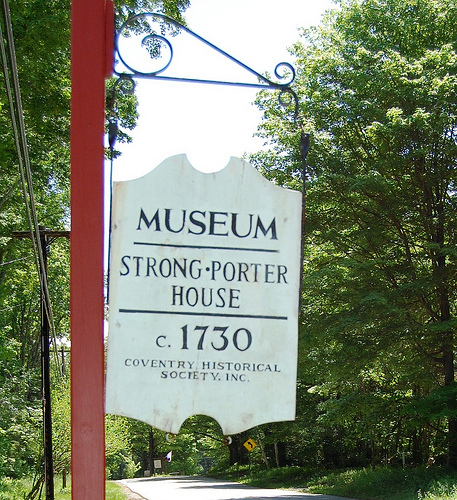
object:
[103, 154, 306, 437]
sign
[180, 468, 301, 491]
shadow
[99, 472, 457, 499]
ground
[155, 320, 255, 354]
year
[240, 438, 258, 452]
sign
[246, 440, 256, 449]
area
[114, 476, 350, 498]
road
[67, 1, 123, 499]
red metal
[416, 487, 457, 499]
grass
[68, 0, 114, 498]
post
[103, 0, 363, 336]
sky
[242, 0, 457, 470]
clump trees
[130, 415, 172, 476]
tree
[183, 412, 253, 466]
tree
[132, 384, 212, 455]
tree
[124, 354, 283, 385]
writing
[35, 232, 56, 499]
pole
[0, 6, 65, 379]
power line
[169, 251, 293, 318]
porter house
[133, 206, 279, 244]
words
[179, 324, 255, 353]
1730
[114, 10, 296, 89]
metal